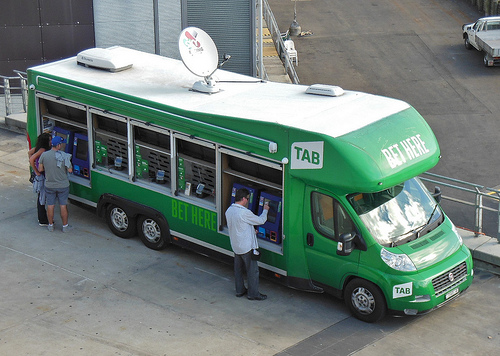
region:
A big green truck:
[21, 40, 476, 325]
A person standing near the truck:
[220, 181, 275, 297]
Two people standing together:
[21, 130, 76, 235]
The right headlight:
[375, 245, 417, 271]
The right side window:
[306, 185, 338, 240]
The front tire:
[340, 275, 390, 325]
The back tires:
[96, 191, 172, 251]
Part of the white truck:
[471, 25, 481, 40]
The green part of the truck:
[335, 145, 353, 170]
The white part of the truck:
[272, 97, 307, 118]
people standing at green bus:
[10, 13, 495, 354]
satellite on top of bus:
[6, 7, 416, 159]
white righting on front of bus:
[324, 105, 441, 201]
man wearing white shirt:
[217, 195, 272, 266]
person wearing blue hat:
[47, 132, 68, 153]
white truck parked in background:
[447, 9, 498, 77]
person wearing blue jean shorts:
[40, 175, 77, 216]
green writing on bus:
[139, 186, 230, 240]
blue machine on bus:
[224, 180, 290, 249]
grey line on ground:
[219, 276, 438, 354]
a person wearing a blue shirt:
[226, 194, 274, 299]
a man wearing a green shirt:
[41, 142, 73, 232]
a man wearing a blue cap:
[43, 136, 74, 231]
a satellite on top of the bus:
[180, 25, 230, 92]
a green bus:
[25, 43, 472, 320]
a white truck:
[462, 17, 498, 73]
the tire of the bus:
[345, 280, 382, 319]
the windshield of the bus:
[347, 179, 444, 241]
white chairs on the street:
[284, 40, 299, 62]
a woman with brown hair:
[26, 135, 48, 227]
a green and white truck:
[8, 18, 480, 330]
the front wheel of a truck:
[340, 277, 387, 324]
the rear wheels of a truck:
[104, 200, 165, 245]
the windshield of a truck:
[351, 183, 443, 240]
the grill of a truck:
[423, 260, 471, 292]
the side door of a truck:
[303, 192, 360, 292]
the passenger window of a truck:
[311, 192, 357, 244]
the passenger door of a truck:
[303, 185, 362, 296]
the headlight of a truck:
[378, 245, 417, 277]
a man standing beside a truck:
[221, 182, 388, 320]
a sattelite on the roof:
[151, 14, 248, 120]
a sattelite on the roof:
[167, 7, 227, 78]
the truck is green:
[7, 27, 458, 354]